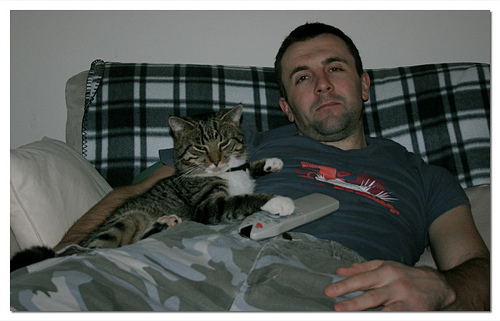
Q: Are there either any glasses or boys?
A: No, there are no glasses or boys.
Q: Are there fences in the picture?
A: No, there are no fences.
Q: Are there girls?
A: No, there are no girls.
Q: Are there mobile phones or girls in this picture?
A: No, there are no girls or mobile phones.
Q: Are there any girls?
A: No, there are no girls.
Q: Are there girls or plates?
A: No, there are no girls or plates.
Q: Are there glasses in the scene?
A: No, there are no glasses.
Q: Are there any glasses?
A: No, there are no glasses.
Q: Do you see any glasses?
A: No, there are no glasses.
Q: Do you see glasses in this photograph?
A: No, there are no glasses.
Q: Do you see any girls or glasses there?
A: No, there are no glasses or girls.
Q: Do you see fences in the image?
A: No, there are no fences.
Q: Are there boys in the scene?
A: No, there are no boys.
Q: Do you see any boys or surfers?
A: No, there are no boys or surfers.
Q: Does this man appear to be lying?
A: Yes, the man is lying.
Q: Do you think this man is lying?
A: Yes, the man is lying.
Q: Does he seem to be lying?
A: Yes, the man is lying.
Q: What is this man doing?
A: The man is lying.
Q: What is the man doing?
A: The man is lying.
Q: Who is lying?
A: The man is lying.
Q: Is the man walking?
A: No, the man is lying.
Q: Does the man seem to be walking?
A: No, the man is lying.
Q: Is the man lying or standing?
A: The man is lying.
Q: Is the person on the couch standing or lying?
A: The man is lying.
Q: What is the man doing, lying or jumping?
A: The man is lying.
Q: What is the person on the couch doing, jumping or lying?
A: The man is lying.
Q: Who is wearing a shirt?
A: The man is wearing a shirt.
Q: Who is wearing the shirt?
A: The man is wearing a shirt.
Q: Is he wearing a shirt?
A: Yes, the man is wearing a shirt.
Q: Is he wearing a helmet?
A: No, the man is wearing a shirt.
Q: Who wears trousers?
A: The man wears trousers.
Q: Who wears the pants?
A: The man wears trousers.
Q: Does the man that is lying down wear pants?
A: Yes, the man wears pants.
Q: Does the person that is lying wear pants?
A: Yes, the man wears pants.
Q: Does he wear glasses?
A: No, the man wears pants.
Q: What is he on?
A: The man is on the couch.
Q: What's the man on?
A: The man is on the couch.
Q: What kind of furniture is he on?
A: The man is on the couch.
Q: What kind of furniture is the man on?
A: The man is on the couch.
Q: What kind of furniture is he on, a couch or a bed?
A: The man is on a couch.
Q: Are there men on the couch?
A: Yes, there is a man on the couch.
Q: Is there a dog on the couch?
A: No, there is a man on the couch.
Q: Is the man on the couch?
A: Yes, the man is on the couch.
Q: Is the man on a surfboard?
A: No, the man is on the couch.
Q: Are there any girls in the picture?
A: No, there are no girls.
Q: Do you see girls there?
A: No, there are no girls.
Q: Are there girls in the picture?
A: No, there are no girls.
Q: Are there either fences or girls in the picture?
A: No, there are no girls or fences.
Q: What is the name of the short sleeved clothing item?
A: The clothing item is a shirt.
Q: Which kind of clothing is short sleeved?
A: The clothing is a shirt.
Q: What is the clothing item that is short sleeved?
A: The clothing item is a shirt.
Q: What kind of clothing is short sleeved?
A: The clothing is a shirt.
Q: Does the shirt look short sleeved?
A: Yes, the shirt is short sleeved.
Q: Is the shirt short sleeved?
A: Yes, the shirt is short sleeved.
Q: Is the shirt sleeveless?
A: No, the shirt is short sleeved.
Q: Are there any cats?
A: Yes, there is a cat.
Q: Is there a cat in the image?
A: Yes, there is a cat.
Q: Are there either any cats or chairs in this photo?
A: Yes, there is a cat.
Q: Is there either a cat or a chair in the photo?
A: Yes, there is a cat.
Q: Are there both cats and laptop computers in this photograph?
A: No, there is a cat but no laptops.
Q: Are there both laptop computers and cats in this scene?
A: No, there is a cat but no laptops.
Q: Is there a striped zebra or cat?
A: Yes, there is a striped cat.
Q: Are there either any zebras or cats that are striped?
A: Yes, the cat is striped.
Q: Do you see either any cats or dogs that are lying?
A: Yes, the cat is lying.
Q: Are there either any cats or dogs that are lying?
A: Yes, the cat is lying.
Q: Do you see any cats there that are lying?
A: Yes, there is a cat that is lying.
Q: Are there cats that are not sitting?
A: Yes, there is a cat that is lying.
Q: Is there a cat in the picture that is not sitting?
A: Yes, there is a cat that is lying.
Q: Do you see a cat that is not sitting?
A: Yes, there is a cat that is lying .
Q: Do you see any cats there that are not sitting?
A: Yes, there is a cat that is lying .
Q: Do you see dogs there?
A: No, there are no dogs.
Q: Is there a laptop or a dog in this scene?
A: No, there are no dogs or laptops.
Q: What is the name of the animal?
A: The animal is a cat.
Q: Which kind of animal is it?
A: The animal is a cat.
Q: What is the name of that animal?
A: This is a cat.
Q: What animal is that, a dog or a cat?
A: This is a cat.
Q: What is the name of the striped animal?
A: The animal is a cat.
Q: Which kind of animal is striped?
A: The animal is a cat.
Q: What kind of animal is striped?
A: The animal is a cat.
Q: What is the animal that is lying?
A: The animal is a cat.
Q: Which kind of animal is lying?
A: The animal is a cat.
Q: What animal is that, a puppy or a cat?
A: That is a cat.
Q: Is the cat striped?
A: Yes, the cat is striped.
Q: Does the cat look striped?
A: Yes, the cat is striped.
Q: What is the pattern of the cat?
A: The cat is striped.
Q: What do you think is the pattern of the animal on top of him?
A: The cat is striped.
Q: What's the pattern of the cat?
A: The cat is striped.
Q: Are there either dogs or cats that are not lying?
A: No, there is a cat but it is lying.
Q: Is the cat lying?
A: Yes, the cat is lying.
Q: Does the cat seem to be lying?
A: Yes, the cat is lying.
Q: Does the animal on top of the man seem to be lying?
A: Yes, the cat is lying.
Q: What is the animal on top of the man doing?
A: The cat is lying.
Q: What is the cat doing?
A: The cat is lying.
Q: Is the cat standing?
A: No, the cat is lying.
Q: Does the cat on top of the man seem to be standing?
A: No, the cat is lying.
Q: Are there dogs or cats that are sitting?
A: No, there is a cat but it is lying.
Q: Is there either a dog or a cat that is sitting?
A: No, there is a cat but it is lying.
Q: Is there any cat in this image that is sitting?
A: No, there is a cat but it is lying.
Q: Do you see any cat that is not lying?
A: No, there is a cat but it is lying.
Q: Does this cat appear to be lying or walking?
A: The cat is lying.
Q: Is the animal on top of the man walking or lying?
A: The cat is lying.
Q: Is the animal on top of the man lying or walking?
A: The cat is lying.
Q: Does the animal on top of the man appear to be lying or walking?
A: The cat is lying.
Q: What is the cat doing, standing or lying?
A: The cat is lying.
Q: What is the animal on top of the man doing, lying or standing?
A: The cat is lying.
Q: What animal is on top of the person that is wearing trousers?
A: The cat is on top of the man.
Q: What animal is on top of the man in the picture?
A: The animal is a cat.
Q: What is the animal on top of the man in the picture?
A: The animal is a cat.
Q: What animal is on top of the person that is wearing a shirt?
A: The animal is a cat.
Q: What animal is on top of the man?
A: The animal is a cat.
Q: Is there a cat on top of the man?
A: Yes, there is a cat on top of the man.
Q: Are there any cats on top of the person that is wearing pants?
A: Yes, there is a cat on top of the man.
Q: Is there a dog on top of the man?
A: No, there is a cat on top of the man.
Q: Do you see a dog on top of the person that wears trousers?
A: No, there is a cat on top of the man.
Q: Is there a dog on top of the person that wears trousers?
A: No, there is a cat on top of the man.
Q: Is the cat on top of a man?
A: Yes, the cat is on top of a man.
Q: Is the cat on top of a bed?
A: No, the cat is on top of a man.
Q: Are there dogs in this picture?
A: No, there are no dogs.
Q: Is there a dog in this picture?
A: No, there are no dogs.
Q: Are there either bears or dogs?
A: No, there are no dogs or bears.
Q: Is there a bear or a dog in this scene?
A: No, there are no dogs or bears.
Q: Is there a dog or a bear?
A: No, there are no dogs or bears.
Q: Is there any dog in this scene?
A: No, there are no dogs.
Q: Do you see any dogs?
A: No, there are no dogs.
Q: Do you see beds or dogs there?
A: No, there are no dogs or beds.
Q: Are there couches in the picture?
A: Yes, there is a couch.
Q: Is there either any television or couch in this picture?
A: Yes, there is a couch.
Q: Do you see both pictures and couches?
A: No, there is a couch but no pictures.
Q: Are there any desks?
A: No, there are no desks.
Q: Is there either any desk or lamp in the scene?
A: No, there are no desks or lamps.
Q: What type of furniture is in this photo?
A: The furniture is a couch.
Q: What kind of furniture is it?
A: The piece of furniture is a couch.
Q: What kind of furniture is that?
A: This is a couch.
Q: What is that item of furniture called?
A: This is a couch.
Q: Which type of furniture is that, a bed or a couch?
A: This is a couch.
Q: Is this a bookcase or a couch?
A: This is a couch.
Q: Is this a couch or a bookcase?
A: This is a couch.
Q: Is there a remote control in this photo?
A: Yes, there is a remote control.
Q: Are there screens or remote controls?
A: Yes, there is a remote control.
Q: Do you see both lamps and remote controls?
A: No, there is a remote control but no lamps.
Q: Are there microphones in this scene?
A: No, there are no microphones.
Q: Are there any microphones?
A: No, there are no microphones.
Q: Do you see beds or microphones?
A: No, there are no microphones or beds.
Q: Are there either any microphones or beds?
A: No, there are no microphones or beds.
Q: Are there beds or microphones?
A: No, there are no microphones or beds.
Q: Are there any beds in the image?
A: No, there are no beds.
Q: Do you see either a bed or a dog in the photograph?
A: No, there are no beds or dogs.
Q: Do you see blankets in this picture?
A: Yes, there is a blanket.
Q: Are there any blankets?
A: Yes, there is a blanket.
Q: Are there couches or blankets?
A: Yes, there is a blanket.